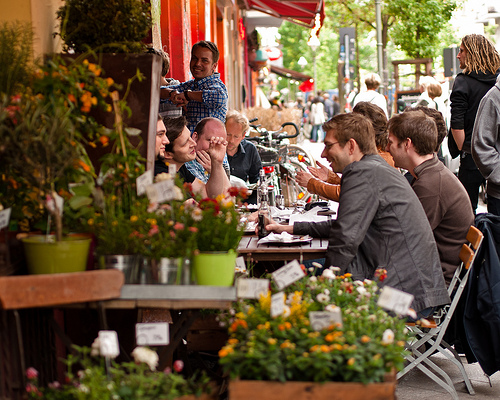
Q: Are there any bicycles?
A: Yes, there is a bicycle.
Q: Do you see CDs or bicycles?
A: Yes, there is a bicycle.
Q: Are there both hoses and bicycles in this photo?
A: No, there is a bicycle but no hoses.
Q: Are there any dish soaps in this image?
A: No, there are no dish soaps.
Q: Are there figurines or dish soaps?
A: No, there are no dish soaps or figurines.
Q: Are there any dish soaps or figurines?
A: No, there are no dish soaps or figurines.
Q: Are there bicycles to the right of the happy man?
A: Yes, there is a bicycle to the right of the man.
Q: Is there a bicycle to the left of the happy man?
A: No, the bicycle is to the right of the man.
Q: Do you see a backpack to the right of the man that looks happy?
A: No, there is a bicycle to the right of the man.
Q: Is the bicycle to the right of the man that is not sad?
A: Yes, the bicycle is to the right of the man.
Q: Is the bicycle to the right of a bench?
A: No, the bicycle is to the right of the man.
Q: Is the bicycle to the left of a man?
A: No, the bicycle is to the right of a man.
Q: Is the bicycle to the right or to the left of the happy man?
A: The bicycle is to the right of the man.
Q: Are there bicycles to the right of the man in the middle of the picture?
A: Yes, there is a bicycle to the right of the man.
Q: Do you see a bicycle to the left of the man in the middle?
A: No, the bicycle is to the right of the man.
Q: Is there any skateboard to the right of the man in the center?
A: No, there is a bicycle to the right of the man.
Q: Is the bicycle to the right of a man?
A: Yes, the bicycle is to the right of a man.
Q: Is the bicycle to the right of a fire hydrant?
A: No, the bicycle is to the right of a man.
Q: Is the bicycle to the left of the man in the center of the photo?
A: No, the bicycle is to the right of the man.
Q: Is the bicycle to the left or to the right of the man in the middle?
A: The bicycle is to the right of the man.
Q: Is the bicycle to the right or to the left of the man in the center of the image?
A: The bicycle is to the right of the man.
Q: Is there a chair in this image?
A: Yes, there is a chair.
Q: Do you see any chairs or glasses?
A: Yes, there is a chair.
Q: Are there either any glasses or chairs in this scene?
A: Yes, there is a chair.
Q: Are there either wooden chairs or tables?
A: Yes, there is a wood chair.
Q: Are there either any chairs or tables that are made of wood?
A: Yes, the chair is made of wood.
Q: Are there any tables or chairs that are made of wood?
A: Yes, the chair is made of wood.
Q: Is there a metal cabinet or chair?
A: Yes, there is a metal chair.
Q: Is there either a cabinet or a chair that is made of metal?
A: Yes, the chair is made of metal.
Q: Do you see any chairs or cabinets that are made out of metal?
A: Yes, the chair is made of metal.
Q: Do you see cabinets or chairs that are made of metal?
A: Yes, the chair is made of metal.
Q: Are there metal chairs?
A: Yes, there is a chair that is made of metal.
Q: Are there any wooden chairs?
A: Yes, there is a wood chair.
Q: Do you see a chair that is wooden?
A: Yes, there is a chair that is wooden.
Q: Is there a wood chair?
A: Yes, there is a chair that is made of wood.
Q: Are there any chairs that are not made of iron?
A: Yes, there is a chair that is made of wood.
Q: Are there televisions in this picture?
A: No, there are no televisions.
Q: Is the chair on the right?
A: Yes, the chair is on the right of the image.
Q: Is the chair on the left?
A: No, the chair is on the right of the image.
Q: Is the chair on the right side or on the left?
A: The chair is on the right of the image.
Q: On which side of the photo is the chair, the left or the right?
A: The chair is on the right of the image.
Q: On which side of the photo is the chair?
A: The chair is on the right of the image.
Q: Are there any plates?
A: No, there are no plates.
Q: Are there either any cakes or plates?
A: No, there are no plates or cakes.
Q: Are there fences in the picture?
A: No, there are no fences.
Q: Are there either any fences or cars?
A: No, there are no fences or cars.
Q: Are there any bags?
A: No, there are no bags.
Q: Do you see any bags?
A: No, there are no bags.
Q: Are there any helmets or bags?
A: No, there are no bags or helmets.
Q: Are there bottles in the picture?
A: Yes, there is a bottle.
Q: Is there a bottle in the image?
A: Yes, there is a bottle.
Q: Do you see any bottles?
A: Yes, there is a bottle.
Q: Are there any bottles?
A: Yes, there is a bottle.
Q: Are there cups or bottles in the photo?
A: Yes, there is a bottle.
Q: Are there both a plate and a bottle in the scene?
A: No, there is a bottle but no plates.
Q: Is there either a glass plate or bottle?
A: Yes, there is a glass bottle.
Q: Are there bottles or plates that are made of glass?
A: Yes, the bottle is made of glass.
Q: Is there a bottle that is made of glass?
A: Yes, there is a bottle that is made of glass.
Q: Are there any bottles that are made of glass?
A: Yes, there is a bottle that is made of glass.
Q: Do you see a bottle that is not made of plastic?
A: Yes, there is a bottle that is made of glass.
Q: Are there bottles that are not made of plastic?
A: Yes, there is a bottle that is made of glass.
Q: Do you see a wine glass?
A: No, there are no wine glasses.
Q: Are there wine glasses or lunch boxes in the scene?
A: No, there are no wine glasses or lunch boxes.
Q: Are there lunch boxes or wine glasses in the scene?
A: No, there are no wine glasses or lunch boxes.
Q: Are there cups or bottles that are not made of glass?
A: No, there is a bottle but it is made of glass.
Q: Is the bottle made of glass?
A: Yes, the bottle is made of glass.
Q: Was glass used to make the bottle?
A: Yes, the bottle is made of glass.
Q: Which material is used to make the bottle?
A: The bottle is made of glass.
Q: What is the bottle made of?
A: The bottle is made of glass.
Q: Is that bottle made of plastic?
A: No, the bottle is made of glass.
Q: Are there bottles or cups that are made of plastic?
A: No, there is a bottle but it is made of glass.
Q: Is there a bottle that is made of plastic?
A: No, there is a bottle but it is made of glass.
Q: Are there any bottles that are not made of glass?
A: No, there is a bottle but it is made of glass.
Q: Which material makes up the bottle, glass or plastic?
A: The bottle is made of glass.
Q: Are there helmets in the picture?
A: No, there are no helmets.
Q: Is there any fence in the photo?
A: No, there are no fences.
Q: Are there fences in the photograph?
A: No, there are no fences.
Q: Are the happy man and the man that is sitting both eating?
A: Yes, both the man and the man are eating.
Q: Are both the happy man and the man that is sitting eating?
A: Yes, both the man and the man are eating.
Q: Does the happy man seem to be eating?
A: Yes, the man is eating.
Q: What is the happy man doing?
A: The man is eating.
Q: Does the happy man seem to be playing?
A: No, the man is eating.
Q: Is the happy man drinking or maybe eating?
A: The man is eating.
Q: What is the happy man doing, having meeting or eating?
A: The man is eating.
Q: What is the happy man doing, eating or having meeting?
A: The man is eating.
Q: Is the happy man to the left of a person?
A: Yes, the man is to the left of a person.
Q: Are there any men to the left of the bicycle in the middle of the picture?
A: Yes, there is a man to the left of the bicycle.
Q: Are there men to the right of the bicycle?
A: No, the man is to the left of the bicycle.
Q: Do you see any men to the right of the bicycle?
A: No, the man is to the left of the bicycle.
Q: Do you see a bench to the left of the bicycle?
A: No, there is a man to the left of the bicycle.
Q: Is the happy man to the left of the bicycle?
A: Yes, the man is to the left of the bicycle.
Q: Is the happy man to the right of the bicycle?
A: No, the man is to the left of the bicycle.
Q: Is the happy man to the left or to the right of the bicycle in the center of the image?
A: The man is to the left of the bicycle.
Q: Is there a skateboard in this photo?
A: No, there are no skateboards.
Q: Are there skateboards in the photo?
A: No, there are no skateboards.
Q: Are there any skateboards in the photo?
A: No, there are no skateboards.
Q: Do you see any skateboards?
A: No, there are no skateboards.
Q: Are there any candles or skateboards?
A: No, there are no skateboards or candles.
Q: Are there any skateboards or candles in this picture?
A: No, there are no skateboards or candles.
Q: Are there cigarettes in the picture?
A: No, there are no cigarettes.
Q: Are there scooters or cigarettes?
A: No, there are no cigarettes or scooters.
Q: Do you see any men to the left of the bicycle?
A: Yes, there is a man to the left of the bicycle.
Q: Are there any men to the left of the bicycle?
A: Yes, there is a man to the left of the bicycle.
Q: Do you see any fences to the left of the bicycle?
A: No, there is a man to the left of the bicycle.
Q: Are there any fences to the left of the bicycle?
A: No, there is a man to the left of the bicycle.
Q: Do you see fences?
A: No, there are no fences.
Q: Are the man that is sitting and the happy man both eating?
A: Yes, both the man and the man are eating.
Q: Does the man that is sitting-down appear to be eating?
A: Yes, the man is eating.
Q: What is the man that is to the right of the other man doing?
A: The man is eating.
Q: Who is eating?
A: The man is eating.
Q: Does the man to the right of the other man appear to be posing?
A: No, the man is eating.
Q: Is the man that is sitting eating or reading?
A: The man is eating.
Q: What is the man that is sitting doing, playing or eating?
A: The man is eating.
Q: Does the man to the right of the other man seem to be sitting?
A: Yes, the man is sitting.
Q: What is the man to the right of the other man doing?
A: The man is sitting.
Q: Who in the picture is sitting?
A: The man is sitting.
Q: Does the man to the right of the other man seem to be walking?
A: No, the man is sitting.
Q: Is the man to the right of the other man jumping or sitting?
A: The man is sitting.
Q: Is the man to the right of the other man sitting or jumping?
A: The man is sitting.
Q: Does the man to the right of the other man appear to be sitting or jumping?
A: The man is sitting.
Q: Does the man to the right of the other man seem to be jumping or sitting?
A: The man is sitting.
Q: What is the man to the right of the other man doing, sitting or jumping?
A: The man is sitting.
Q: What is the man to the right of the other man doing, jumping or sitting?
A: The man is sitting.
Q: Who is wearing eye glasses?
A: The man is wearing eye glasses.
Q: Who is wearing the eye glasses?
A: The man is wearing eye glasses.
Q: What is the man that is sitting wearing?
A: The man is wearing eyeglasses.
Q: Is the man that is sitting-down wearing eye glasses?
A: Yes, the man is wearing eye glasses.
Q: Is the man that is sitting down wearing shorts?
A: No, the man is wearing eye glasses.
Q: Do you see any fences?
A: No, there are no fences.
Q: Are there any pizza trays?
A: No, there are no pizza trays.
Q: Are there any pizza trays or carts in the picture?
A: No, there are no pizza trays or carts.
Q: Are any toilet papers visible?
A: No, there are no toilet papers.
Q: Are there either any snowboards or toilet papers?
A: No, there are no toilet papers or snowboards.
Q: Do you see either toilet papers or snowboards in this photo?
A: No, there are no toilet papers or snowboards.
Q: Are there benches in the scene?
A: No, there are no benches.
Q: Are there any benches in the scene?
A: No, there are no benches.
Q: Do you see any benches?
A: No, there are no benches.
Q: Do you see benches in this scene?
A: No, there are no benches.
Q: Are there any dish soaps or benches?
A: No, there are no benches or dish soaps.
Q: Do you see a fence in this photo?
A: No, there are no fences.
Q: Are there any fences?
A: No, there are no fences.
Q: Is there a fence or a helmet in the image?
A: No, there are no fences or helmets.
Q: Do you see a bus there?
A: No, there are no buses.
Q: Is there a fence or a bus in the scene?
A: No, there are no buses or fences.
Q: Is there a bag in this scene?
A: No, there are no bags.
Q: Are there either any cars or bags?
A: No, there are no bags or cars.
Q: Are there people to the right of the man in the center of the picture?
A: Yes, there is a person to the right of the man.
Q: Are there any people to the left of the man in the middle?
A: No, the person is to the right of the man.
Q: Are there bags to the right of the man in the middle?
A: No, there is a person to the right of the man.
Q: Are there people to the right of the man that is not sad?
A: Yes, there is a person to the right of the man.